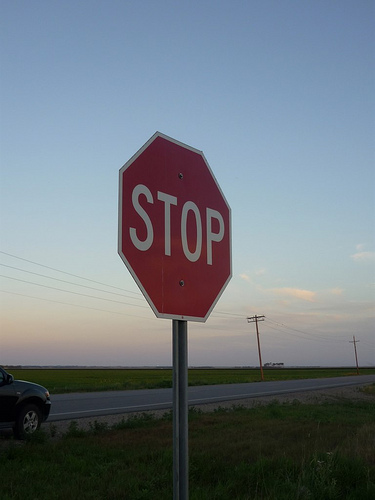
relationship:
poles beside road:
[251, 321, 272, 377] [21, 383, 203, 423]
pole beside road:
[346, 334, 363, 368] [21, 383, 203, 423]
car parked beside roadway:
[0, 362, 52, 439] [2, 379, 371, 422]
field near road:
[3, 361, 347, 392] [0, 372, 374, 440]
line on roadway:
[49, 377, 374, 417] [77, 361, 330, 401]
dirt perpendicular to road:
[75, 382, 360, 493] [42, 375, 367, 418]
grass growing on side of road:
[2, 367, 372, 497] [21, 372, 359, 423]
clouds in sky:
[253, 271, 369, 356] [2, 2, 371, 357]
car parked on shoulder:
[0, 362, 52, 439] [0, 381, 373, 446]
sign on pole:
[118, 132, 234, 323] [169, 318, 189, 498]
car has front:
[0, 362, 52, 439] [42, 385, 51, 421]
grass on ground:
[11, 400, 362, 491] [68, 408, 363, 494]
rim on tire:
[25, 408, 38, 430] [12, 398, 46, 438]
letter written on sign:
[126, 178, 155, 253] [82, 114, 257, 339]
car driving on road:
[0, 362, 52, 439] [51, 370, 374, 420]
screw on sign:
[178, 172, 182, 179] [116, 130, 232, 323]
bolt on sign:
[180, 280, 184, 286] [116, 130, 232, 323]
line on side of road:
[49, 377, 374, 417] [50, 373, 373, 422]